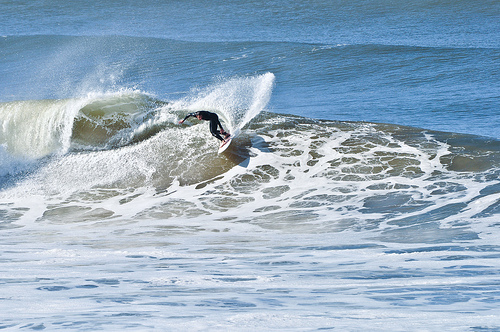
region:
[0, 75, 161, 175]
a big white wave.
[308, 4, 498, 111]
a dark blue ocean.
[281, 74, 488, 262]
a white and blue sea.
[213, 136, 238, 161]
a pink surfboard.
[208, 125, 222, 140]
a man is wearing black pants.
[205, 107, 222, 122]
a man is wearing black shirt.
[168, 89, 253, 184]
a man is surfing in the ocean.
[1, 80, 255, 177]
a man is surfing on the big waves.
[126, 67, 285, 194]
a man is surfing on the huge sea.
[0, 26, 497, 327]
a man is surfing in the beautiful water.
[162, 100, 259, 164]
Man who is surfing.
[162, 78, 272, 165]
Man riding a wave.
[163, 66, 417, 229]
Wave under the surfer.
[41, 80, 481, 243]
Waves in the ocean.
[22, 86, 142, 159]
White caps on the waves.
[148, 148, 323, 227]
Foam on the water.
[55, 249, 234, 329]
Ripples in the water.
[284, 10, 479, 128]
Wave building in the background.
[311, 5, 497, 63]
Calm ocean in the background.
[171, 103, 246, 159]
Person in a black wetsuit.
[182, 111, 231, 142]
a surfer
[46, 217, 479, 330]
the water is blue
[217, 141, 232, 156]
a surfboard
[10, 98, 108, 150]
a wave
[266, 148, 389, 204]
the water is white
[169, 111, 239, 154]
the person is wearing black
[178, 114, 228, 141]
the persons hand is up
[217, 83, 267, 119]
a splash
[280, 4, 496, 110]
the water is blue and clear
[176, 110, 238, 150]
surfer is on the surfboard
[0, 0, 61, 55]
white clouds against blue sky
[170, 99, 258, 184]
person surfing in ocean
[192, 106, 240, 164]
person wearing wet suit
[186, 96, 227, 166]
person wearing black wet suit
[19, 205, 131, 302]
white and blue waves in ocean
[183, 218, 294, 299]
white and blue waves in ocean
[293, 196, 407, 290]
white and blue waves in ocean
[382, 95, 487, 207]
white and blue waves in ocean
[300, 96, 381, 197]
white and blue waves in ocean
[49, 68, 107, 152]
white and blue waves in ocean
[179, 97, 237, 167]
Person surfing on the water.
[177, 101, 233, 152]
Black wet suit on person.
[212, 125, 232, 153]
Bare feet on surfboard.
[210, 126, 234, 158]
White surfboard on water.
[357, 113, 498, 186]
Gray colored waves in water.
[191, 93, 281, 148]
Spray of water from surfboard breaking surface.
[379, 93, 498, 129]
Blue water in the background.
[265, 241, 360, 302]
White foam on top of the water.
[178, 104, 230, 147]
Person has long sleeves on shirt.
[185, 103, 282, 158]
Person has brown hair.